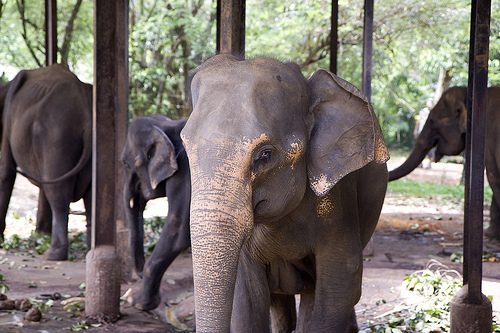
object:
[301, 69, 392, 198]
ear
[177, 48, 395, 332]
elephant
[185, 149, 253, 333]
trunk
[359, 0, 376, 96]
post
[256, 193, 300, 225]
jaw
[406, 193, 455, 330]
ground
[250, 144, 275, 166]
eye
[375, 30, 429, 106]
plant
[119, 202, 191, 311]
leg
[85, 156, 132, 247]
metal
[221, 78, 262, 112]
fur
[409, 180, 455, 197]
grass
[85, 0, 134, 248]
pillar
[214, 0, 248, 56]
pole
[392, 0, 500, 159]
tree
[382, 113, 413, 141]
leaves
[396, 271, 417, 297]
leaves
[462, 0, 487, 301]
beam